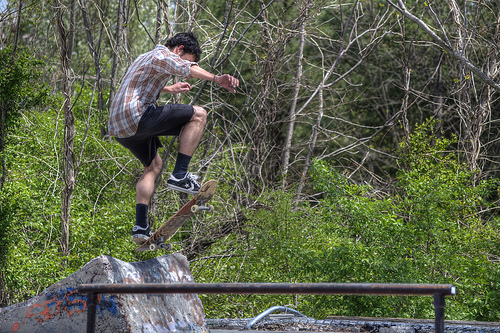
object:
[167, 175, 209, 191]
black shoes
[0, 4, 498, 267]
trees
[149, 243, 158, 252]
wheel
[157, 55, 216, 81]
arms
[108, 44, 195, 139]
shirt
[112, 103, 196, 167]
shorts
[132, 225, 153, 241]
shoes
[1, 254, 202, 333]
man rock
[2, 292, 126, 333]
graffiti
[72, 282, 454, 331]
rail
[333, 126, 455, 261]
ground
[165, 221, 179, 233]
designs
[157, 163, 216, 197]
converse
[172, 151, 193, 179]
sock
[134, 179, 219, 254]
skateboard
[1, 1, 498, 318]
forest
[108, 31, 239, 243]
man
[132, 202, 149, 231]
socks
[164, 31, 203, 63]
hair